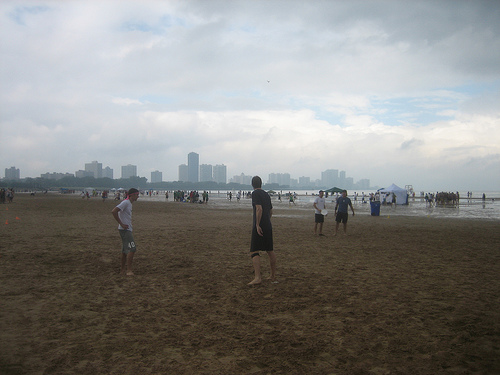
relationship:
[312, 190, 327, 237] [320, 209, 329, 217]
man holding frisbee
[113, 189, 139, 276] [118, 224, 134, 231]
man holding waist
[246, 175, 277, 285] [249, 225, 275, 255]
man has shorts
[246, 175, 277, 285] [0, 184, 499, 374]
person at beach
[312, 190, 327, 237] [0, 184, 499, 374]
man at beach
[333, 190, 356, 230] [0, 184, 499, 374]
person at beach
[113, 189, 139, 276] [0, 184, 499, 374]
man at beach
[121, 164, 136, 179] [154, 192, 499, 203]
building behind water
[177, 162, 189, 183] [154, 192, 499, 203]
building behind water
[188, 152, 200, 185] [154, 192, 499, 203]
building behind water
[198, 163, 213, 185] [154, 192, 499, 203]
building behind water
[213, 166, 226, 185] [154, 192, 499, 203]
building behind water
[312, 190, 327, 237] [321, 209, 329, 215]
man playing frisbee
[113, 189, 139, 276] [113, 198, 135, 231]
man wearing shirt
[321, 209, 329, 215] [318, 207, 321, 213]
frisbee in hand